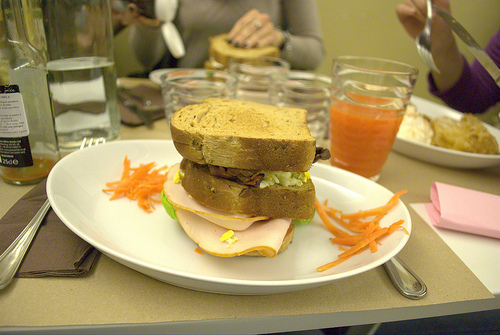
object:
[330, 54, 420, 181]
glass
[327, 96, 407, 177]
orange beverage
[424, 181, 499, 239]
paper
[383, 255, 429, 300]
handle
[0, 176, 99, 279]
napkin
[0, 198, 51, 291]
fork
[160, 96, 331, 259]
bread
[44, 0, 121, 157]
glass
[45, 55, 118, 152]
liquid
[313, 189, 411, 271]
carrots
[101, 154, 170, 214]
carrots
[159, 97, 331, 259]
sandwich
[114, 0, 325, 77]
pitcher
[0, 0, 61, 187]
bottle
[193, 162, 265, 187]
roast beef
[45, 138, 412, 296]
plate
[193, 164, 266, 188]
turkey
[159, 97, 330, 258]
cold cut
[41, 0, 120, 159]
bottle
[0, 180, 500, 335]
table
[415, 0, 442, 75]
fork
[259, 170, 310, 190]
shredded lettuce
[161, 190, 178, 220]
shredded lettuce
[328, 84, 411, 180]
juice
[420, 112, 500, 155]
food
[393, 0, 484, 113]
hand